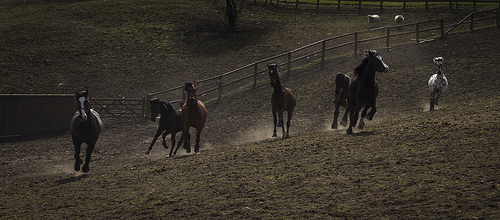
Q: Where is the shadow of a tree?
A: Top center of image.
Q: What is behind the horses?
A: A wooden fence.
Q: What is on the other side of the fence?
A: A green pasture field.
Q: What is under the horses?
A: Green grass and dirt.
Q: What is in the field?
A: Green grass and dirt.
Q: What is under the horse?
A: Dust cloud from running.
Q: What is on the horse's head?
A: A bridle.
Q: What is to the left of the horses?
A: A wooden gate.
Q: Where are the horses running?
A: They running up a hill.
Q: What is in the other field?
A: A couple of sheep.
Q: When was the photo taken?
A: Daytime.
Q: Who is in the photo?
A: Nobody.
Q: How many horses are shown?
A: Seven.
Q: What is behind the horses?
A: A fence.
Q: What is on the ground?
A: Dirt.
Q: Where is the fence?
A: Behind the horses.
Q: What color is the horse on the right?
A: White.